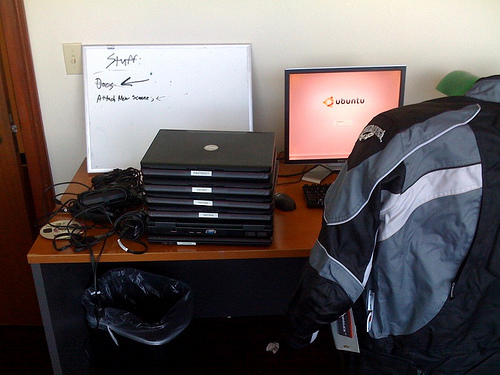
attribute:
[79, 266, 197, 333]
liner — clear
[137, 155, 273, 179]
laptop — stack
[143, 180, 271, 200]
laptop — stack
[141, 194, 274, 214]
laptop — stack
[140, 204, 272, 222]
laptop — stack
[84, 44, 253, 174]
board — white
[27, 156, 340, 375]
table — brown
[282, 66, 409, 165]
monitor — on, pink, partly blocked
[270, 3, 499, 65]
wall — white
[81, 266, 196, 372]
can — black, trash, plastic, clear, empty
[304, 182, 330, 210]
keyboard — black, part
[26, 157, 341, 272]
desk — brown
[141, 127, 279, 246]
laptops — black, closed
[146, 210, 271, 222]
laptop — stacked, black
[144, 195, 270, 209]
laptop — stacked, black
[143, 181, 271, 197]
laptop — stacked, black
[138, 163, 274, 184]
laptop — stacked, black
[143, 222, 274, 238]
laptop — stacked, black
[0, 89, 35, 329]
door — brown, wood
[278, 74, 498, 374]
jacket — grey, black, blue, white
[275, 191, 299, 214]
mouse — black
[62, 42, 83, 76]
light switch — beige, electrical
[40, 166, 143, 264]
cords — jumbled